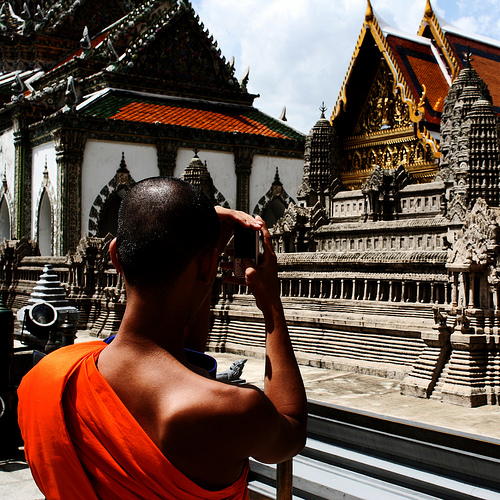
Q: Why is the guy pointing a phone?
A: Take a picture.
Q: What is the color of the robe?
A: Orange.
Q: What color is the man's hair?
A: Black.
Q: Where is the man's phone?
A: His hands.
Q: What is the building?
A: A shrine.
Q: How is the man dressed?
A: Like a monk.